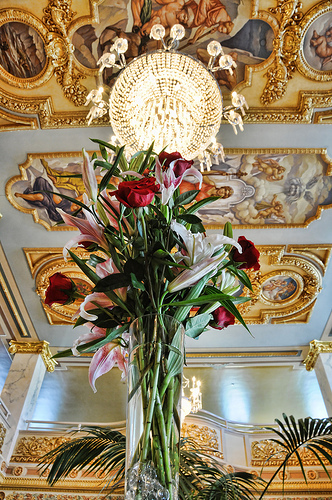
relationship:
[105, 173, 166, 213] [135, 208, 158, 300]
rose on stem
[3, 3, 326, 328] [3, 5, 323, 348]
panels on ceiling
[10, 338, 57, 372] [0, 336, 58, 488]
molding of pillar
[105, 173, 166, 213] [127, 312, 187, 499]
rose in vase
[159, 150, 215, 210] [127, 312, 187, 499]
day lily in vase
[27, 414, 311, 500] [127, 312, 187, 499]
plant fronds behind vase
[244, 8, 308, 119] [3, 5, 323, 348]
decorations on ceiling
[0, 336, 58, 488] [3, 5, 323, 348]
pillar supporting ceiling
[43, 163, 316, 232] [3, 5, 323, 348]
mural on ceiling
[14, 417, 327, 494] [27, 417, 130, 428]
balcony with railing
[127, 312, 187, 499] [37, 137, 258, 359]
vase with flowers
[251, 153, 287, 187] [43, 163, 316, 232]
angel on mural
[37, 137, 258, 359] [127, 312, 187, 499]
bouquet in vase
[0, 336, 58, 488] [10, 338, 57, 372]
pillar with ornamentations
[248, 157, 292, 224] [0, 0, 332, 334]
cherubs on panels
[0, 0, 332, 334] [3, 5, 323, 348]
panels on ceiling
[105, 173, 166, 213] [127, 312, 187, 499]
rose in container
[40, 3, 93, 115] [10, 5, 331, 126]
cornucopias in relief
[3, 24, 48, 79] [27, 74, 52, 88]
painting in frame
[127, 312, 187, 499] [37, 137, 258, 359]
vase of flowers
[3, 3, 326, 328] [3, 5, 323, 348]
fresco on ceiling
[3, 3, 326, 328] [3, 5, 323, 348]
decoration on ceiling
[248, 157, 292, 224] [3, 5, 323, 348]
figures on ceiling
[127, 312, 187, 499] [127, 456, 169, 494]
vase with stones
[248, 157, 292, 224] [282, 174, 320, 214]
cherubs with god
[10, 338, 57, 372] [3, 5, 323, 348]
molding on ceiling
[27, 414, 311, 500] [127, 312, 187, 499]
palm behind vase